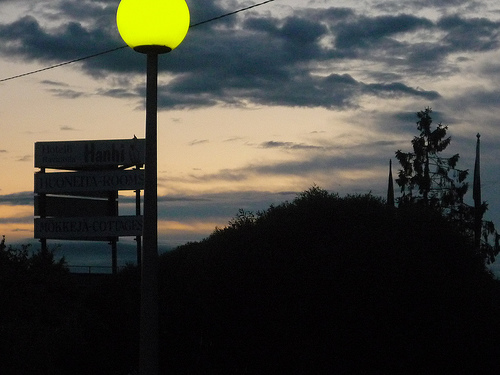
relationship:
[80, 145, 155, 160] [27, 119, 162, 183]
letter on sign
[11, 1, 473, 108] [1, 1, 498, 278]
cloud in sky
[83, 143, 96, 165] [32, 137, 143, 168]
letter on sign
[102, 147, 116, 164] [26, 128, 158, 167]
black letter on sign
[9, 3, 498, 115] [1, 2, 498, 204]
clouds in sky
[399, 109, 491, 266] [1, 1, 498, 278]
tree against sky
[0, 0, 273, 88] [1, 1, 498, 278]
cable in sky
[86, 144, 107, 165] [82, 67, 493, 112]
letter in sign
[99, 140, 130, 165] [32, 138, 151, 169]
letter in sign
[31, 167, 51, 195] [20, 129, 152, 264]
letter in sign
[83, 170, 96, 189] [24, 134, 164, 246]
letter on sign